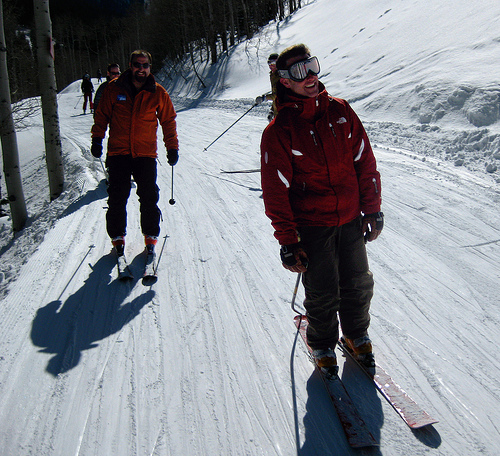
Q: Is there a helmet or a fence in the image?
A: No, there are no fences or helmets.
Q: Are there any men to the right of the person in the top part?
A: Yes, there are men to the right of the person.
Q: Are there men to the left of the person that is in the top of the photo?
A: No, the men are to the right of the person.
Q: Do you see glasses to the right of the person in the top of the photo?
A: No, there are men to the right of the person.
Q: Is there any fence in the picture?
A: No, there are no fences.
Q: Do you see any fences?
A: No, there are no fences.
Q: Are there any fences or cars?
A: No, there are no fences or cars.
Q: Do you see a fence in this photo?
A: No, there are no fences.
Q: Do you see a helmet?
A: No, there are no helmets.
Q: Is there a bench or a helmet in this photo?
A: No, there are no helmets or benches.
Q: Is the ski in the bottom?
A: Yes, the ski is in the bottom of the image.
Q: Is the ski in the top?
A: No, the ski is in the bottom of the image.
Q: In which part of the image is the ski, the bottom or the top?
A: The ski is in the bottom of the image.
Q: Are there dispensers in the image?
A: No, there are no dispensers.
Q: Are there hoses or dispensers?
A: No, there are no dispensers or hoses.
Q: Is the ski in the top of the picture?
A: No, the ski is in the bottom of the image.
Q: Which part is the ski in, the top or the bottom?
A: The ski is in the bottom of the image.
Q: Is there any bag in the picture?
A: No, there are no bags.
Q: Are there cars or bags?
A: No, there are no bags or cars.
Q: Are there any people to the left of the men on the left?
A: Yes, there is a person to the left of the men.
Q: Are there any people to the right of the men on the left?
A: No, the person is to the left of the men.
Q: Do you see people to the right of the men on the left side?
A: No, the person is to the left of the men.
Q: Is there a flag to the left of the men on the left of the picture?
A: No, there is a person to the left of the men.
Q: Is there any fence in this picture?
A: No, there are no fences.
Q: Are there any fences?
A: No, there are no fences.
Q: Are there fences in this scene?
A: No, there are no fences.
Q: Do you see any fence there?
A: No, there are no fences.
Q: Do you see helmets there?
A: No, there are no helmets.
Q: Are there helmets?
A: No, there are no helmets.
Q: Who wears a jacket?
A: The man wears a jacket.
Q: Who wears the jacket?
A: The man wears a jacket.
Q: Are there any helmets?
A: No, there are no helmets.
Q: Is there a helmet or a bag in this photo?
A: No, there are no helmets or bags.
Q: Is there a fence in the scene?
A: No, there are no fences.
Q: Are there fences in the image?
A: No, there are no fences.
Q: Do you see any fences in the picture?
A: No, there are no fences.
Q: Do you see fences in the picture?
A: No, there are no fences.